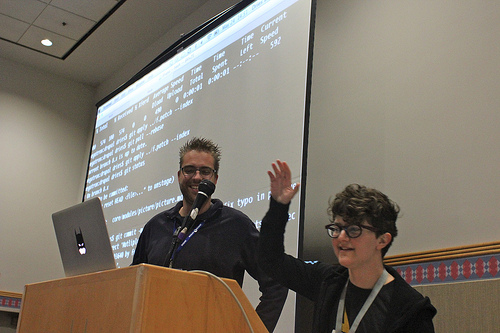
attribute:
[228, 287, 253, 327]
wire — gray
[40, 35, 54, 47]
light — on the ceiling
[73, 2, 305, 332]
display — on the giant screen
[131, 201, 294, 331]
shirt — black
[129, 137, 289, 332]
man — standing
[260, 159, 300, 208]
hand — right hand